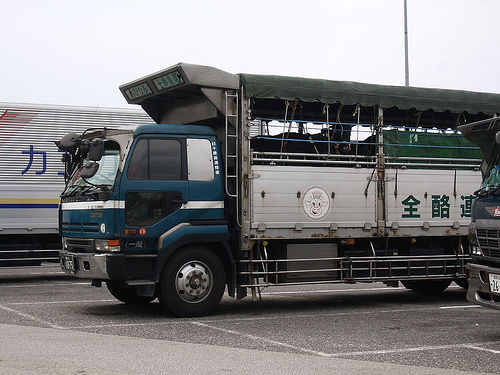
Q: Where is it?
A: This is at the pavement.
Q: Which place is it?
A: It is a pavement.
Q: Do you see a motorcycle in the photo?
A: No, there are no motorcycles.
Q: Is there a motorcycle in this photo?
A: No, there are no motorcycles.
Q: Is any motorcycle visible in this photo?
A: No, there are no motorcycles.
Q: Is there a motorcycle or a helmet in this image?
A: No, there are no motorcycles or helmets.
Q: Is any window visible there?
A: Yes, there is a window.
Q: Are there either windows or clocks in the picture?
A: Yes, there is a window.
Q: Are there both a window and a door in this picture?
A: Yes, there are both a window and a door.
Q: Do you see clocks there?
A: No, there are no clocks.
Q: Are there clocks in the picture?
A: No, there are no clocks.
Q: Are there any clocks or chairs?
A: No, there are no clocks or chairs.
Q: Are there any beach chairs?
A: No, there are no beach chairs.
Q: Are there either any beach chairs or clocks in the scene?
A: No, there are no beach chairs or clocks.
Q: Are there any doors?
A: Yes, there is a door.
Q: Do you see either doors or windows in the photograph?
A: Yes, there is a door.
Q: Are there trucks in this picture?
A: Yes, there is a truck.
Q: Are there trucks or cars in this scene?
A: Yes, there is a truck.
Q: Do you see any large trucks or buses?
A: Yes, there is a large truck.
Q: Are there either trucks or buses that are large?
A: Yes, the truck is large.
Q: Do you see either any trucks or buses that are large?
A: Yes, the truck is large.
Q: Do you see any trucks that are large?
A: Yes, there is a large truck.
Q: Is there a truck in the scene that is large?
A: Yes, there is a truck that is large.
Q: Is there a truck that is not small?
A: Yes, there is a large truck.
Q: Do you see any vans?
A: No, there are no vans.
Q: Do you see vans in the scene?
A: No, there are no vans.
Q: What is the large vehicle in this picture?
A: The vehicle is a truck.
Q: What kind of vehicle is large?
A: The vehicle is a truck.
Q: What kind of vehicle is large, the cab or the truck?
A: The truck is large.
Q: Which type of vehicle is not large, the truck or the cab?
A: The cab is not large.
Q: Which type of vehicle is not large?
A: The vehicle is a taxi.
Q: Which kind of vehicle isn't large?
A: The vehicle is a taxi.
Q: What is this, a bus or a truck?
A: This is a truck.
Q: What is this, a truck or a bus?
A: This is a truck.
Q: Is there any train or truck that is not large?
A: No, there is a truck but it is large.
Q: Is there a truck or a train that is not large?
A: No, there is a truck but it is large.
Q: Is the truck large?
A: Yes, the truck is large.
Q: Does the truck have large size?
A: Yes, the truck is large.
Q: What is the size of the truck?
A: The truck is large.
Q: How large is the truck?
A: The truck is large.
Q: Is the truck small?
A: No, the truck is large.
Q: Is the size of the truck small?
A: No, the truck is large.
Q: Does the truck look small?
A: No, the truck is large.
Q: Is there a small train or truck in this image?
A: No, there is a truck but it is large.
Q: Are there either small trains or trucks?
A: No, there is a truck but it is large.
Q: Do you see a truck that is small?
A: No, there is a truck but it is large.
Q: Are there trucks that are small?
A: No, there is a truck but it is large.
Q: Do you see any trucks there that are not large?
A: No, there is a truck but it is large.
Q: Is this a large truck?
A: Yes, this is a large truck.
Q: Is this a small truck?
A: No, this is a large truck.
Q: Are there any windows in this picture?
A: Yes, there is a window.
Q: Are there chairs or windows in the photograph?
A: Yes, there is a window.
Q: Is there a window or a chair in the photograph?
A: Yes, there is a window.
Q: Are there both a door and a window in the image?
A: Yes, there are both a window and a door.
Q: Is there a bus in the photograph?
A: No, there are no buses.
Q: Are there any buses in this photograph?
A: No, there are no buses.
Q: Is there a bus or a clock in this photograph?
A: No, there are no buses or clocks.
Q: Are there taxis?
A: Yes, there is a taxi.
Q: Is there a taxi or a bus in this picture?
A: Yes, there is a taxi.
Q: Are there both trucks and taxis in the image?
A: Yes, there are both a taxi and a truck.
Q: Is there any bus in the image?
A: No, there are no buses.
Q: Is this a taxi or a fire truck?
A: This is a taxi.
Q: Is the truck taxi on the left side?
A: Yes, the taxi cab is on the left of the image.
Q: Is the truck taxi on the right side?
A: No, the cab is on the left of the image.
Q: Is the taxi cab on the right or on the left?
A: The taxi cab is on the left of the image.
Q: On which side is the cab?
A: The cab is on the left of the image.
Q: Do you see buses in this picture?
A: No, there are no buses.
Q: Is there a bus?
A: No, there are no buses.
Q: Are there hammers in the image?
A: No, there are no hammers.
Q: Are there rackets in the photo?
A: No, there are no rackets.